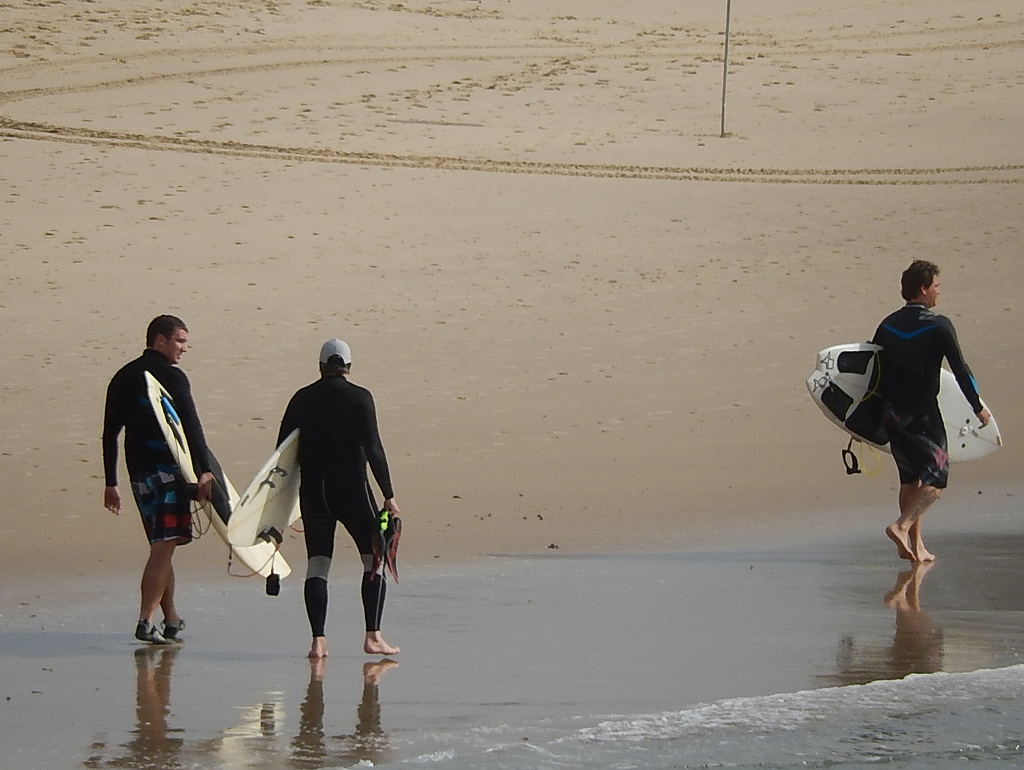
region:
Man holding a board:
[213, 400, 360, 550]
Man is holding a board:
[215, 402, 339, 557]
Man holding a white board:
[219, 411, 333, 558]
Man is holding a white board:
[216, 416, 352, 553]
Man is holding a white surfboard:
[223, 411, 322, 558]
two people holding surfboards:
[60, 268, 435, 572]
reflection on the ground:
[40, 654, 348, 753]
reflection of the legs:
[288, 641, 415, 766]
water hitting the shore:
[707, 630, 919, 764]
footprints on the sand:
[351, 19, 718, 196]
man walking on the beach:
[820, 241, 998, 589]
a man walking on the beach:
[260, 279, 431, 682]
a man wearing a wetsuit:
[783, 215, 1008, 566]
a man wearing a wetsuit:
[273, 353, 435, 611]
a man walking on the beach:
[735, 187, 1018, 457]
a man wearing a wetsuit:
[807, 192, 989, 761]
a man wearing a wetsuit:
[222, 293, 432, 717]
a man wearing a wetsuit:
[62, 316, 277, 573]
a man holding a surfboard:
[289, 301, 401, 628]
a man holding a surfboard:
[778, 216, 1006, 760]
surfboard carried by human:
[134, 367, 296, 584]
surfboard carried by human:
[226, 415, 343, 555]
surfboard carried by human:
[804, 335, 1005, 468]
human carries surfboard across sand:
[99, 308, 293, 650]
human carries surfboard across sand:
[223, 330, 411, 657]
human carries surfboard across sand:
[807, 260, 1003, 568]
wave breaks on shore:
[375, 662, 1020, 767]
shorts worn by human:
[125, 469, 196, 545]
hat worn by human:
[317, 335, 352, 373]